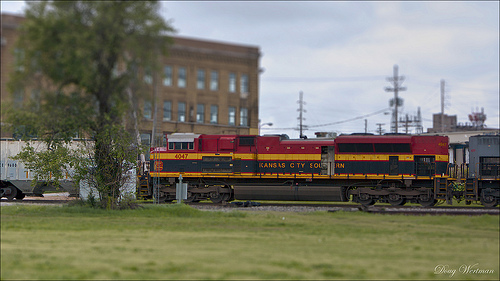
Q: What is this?
A: A train.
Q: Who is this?
A: No one.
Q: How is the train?
A: In motion.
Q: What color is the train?
A: Red.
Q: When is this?
A: Daytime.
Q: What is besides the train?
A: A building.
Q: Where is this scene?
A: Near a train station.